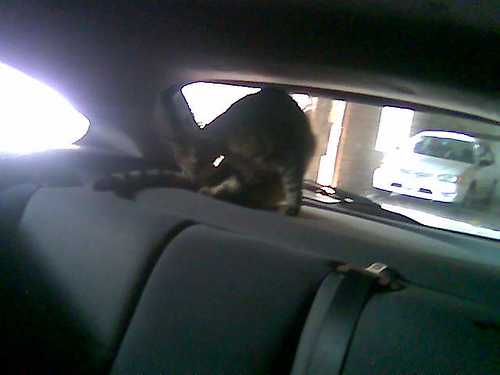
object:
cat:
[95, 92, 312, 215]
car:
[4, 3, 498, 372]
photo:
[0, 0, 499, 375]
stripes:
[286, 183, 298, 192]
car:
[371, 129, 493, 206]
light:
[180, 78, 245, 127]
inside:
[4, 6, 490, 369]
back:
[148, 77, 500, 240]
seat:
[0, 188, 161, 375]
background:
[230, 70, 500, 234]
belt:
[307, 264, 380, 373]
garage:
[334, 111, 500, 226]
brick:
[337, 102, 383, 191]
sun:
[4, 66, 90, 149]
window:
[1, 68, 91, 151]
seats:
[157, 225, 303, 375]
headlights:
[434, 172, 461, 184]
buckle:
[364, 260, 390, 276]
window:
[181, 80, 500, 230]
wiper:
[304, 176, 383, 213]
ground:
[423, 201, 499, 222]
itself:
[91, 86, 316, 213]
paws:
[282, 204, 302, 218]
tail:
[90, 168, 190, 195]